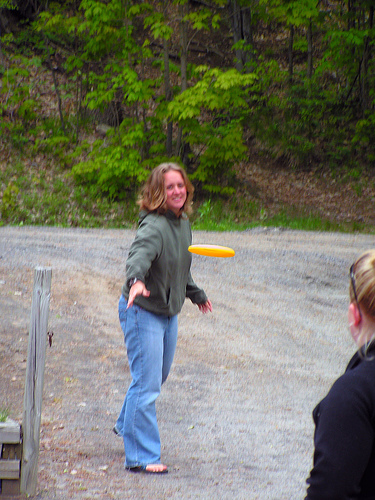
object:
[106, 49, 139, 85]
green leaves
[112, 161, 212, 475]
girl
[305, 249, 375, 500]
girl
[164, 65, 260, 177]
leaves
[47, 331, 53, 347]
key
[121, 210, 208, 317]
hoodie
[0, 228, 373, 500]
dirveway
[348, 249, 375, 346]
head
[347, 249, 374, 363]
hair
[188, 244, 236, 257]
flying disc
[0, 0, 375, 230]
bushes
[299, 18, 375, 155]
leaves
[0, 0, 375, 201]
tree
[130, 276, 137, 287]
watch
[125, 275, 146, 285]
wrist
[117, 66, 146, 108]
leaves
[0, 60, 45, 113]
green leaves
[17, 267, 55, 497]
fence post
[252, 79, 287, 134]
leaves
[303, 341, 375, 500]
top